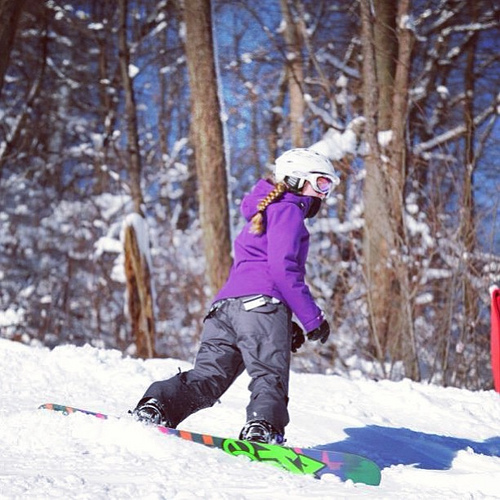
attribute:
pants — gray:
[144, 297, 299, 442]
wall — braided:
[442, 127, 475, 146]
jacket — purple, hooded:
[221, 186, 316, 299]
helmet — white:
[270, 145, 342, 198]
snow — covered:
[14, 330, 485, 480]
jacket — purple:
[212, 179, 324, 332]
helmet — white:
[262, 137, 378, 214]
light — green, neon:
[410, 288, 444, 333]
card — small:
[241, 292, 266, 309]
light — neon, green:
[225, 184, 281, 224]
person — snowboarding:
[133, 138, 335, 472]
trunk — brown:
[183, 0, 233, 301]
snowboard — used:
[39, 400, 381, 488]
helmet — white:
[269, 145, 341, 203]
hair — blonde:
[250, 183, 284, 232]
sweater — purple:
[211, 172, 325, 334]